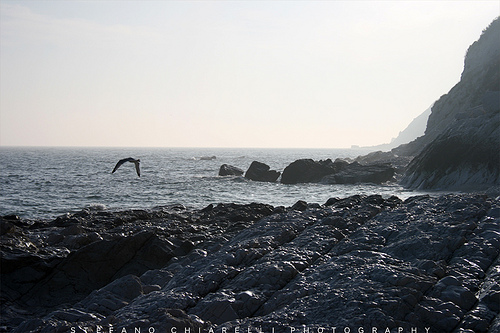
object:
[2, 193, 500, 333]
rock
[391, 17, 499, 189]
cliff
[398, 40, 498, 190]
crags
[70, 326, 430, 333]
name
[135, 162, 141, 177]
wing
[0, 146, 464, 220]
water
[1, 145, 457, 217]
ocean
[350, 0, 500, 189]
mountain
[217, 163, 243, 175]
boulder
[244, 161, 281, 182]
boulder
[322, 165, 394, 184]
boulder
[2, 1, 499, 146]
sky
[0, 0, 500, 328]
outside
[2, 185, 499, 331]
beach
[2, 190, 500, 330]
rocky shore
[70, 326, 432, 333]
photography studio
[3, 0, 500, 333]
shot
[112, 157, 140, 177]
bird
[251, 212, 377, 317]
crevices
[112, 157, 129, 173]
wing